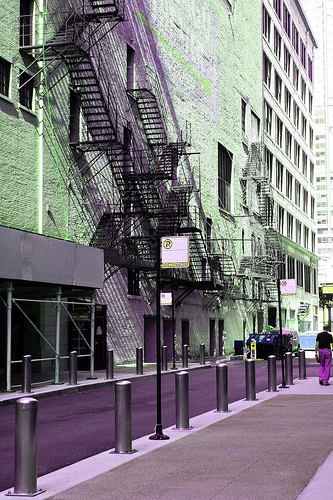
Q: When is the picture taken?
A: Daytime.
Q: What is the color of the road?
A: Grey.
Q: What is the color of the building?
A: Green.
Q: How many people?
A: 1.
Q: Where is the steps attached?
A: To the wall of the building.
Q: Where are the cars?
A: Sides of the road.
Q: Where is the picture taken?
A: On the side of a green and purple building.